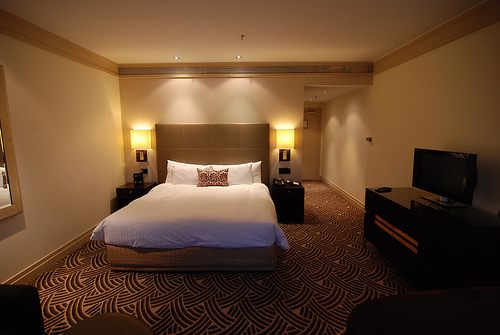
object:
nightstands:
[113, 169, 315, 224]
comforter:
[90, 178, 290, 252]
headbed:
[155, 123, 272, 184]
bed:
[89, 122, 301, 273]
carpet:
[32, 269, 421, 332]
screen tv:
[410, 145, 478, 204]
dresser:
[350, 180, 488, 274]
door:
[301, 102, 322, 180]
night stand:
[266, 176, 310, 225]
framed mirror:
[1, 65, 26, 222]